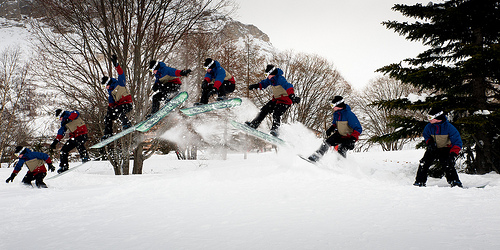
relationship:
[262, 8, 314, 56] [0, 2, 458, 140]
clouds are in sky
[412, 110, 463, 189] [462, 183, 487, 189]
guy on board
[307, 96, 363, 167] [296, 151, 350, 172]
guy on board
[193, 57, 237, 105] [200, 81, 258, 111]
guy on board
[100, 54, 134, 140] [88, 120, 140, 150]
guy riding board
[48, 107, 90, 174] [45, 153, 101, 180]
man riding board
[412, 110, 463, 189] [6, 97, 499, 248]
guy standing snow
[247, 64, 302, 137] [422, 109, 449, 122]
guy wearing goggles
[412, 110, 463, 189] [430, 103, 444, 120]
guy wearing hat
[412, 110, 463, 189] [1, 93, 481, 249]
guy sliding hill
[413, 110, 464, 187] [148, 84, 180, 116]
guy wearing skipants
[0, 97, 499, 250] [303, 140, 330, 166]
snow covered leg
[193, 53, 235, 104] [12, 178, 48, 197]
guy bent snowboard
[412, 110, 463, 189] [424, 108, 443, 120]
guy wearing goggles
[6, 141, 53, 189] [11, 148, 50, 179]
person wearing clothes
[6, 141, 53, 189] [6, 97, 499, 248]
person in snow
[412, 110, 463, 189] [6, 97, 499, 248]
guy in snow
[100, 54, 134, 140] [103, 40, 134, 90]
guy has arm